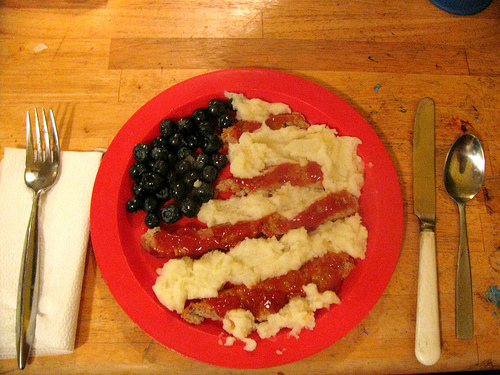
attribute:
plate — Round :
[113, 68, 430, 345]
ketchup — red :
[230, 111, 294, 138]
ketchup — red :
[226, 163, 323, 186]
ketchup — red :
[151, 190, 353, 253]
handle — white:
[403, 229, 448, 367]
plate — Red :
[93, 61, 410, 370]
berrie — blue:
[160, 117, 177, 139]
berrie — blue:
[208, 151, 226, 166]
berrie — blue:
[156, 201, 178, 220]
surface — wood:
[1, 1, 478, 367]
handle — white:
[410, 223, 442, 362]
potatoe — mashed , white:
[230, 123, 370, 192]